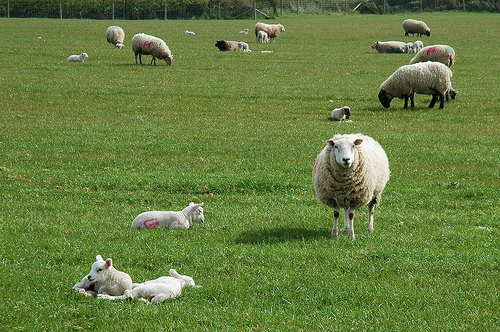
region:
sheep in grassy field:
[288, 119, 387, 248]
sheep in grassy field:
[123, 200, 214, 247]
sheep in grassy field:
[78, 254, 128, 308]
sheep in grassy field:
[151, 265, 195, 310]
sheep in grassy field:
[316, 97, 356, 121]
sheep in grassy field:
[380, 65, 456, 115]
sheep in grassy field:
[411, 45, 459, 62]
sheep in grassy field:
[132, 37, 173, 69]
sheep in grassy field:
[68, 49, 88, 64]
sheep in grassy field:
[98, 14, 122, 56]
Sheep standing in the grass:
[311, 132, 391, 239]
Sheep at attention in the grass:
[308, 132, 392, 237]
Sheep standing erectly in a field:
[309, 132, 392, 238]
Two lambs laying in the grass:
[68, 247, 203, 309]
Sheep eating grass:
[128, 30, 177, 70]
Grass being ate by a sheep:
[130, 31, 175, 67]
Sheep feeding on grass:
[128, 31, 175, 66]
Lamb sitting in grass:
[66, 50, 88, 63]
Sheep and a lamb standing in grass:
[252, 19, 287, 46]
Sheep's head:
[325, 136, 363, 169]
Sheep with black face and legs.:
[375, 60, 455, 110]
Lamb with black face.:
[326, 102, 348, 117]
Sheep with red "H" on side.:
[130, 30, 175, 65]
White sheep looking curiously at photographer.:
[307, 130, 387, 240]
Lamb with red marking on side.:
[129, 199, 206, 232]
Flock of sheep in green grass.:
[64, 18, 461, 306]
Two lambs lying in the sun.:
[72, 252, 204, 307]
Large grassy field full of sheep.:
[1, 16, 498, 328]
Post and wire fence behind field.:
[1, 0, 499, 17]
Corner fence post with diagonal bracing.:
[236, 0, 271, 18]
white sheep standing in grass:
[302, 131, 404, 242]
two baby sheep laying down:
[73, 250, 230, 310]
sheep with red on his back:
[416, 40, 459, 62]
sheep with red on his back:
[128, 30, 185, 72]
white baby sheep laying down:
[65, 45, 97, 68]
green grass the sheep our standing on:
[171, 87, 280, 190]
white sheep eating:
[369, 59, 457, 124]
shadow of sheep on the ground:
[230, 206, 330, 260]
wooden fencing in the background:
[15, 0, 226, 18]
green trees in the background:
[356, 2, 498, 12]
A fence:
[1, 0, 399, 19]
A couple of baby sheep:
[70, 250, 211, 317]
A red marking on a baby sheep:
[141, 214, 163, 229]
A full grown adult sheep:
[309, 125, 394, 247]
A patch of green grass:
[310, 257, 420, 321]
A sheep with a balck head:
[376, 59, 451, 110]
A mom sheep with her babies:
[369, 36, 423, 55]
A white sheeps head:
[324, 137, 365, 169]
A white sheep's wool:
[348, 172, 374, 189]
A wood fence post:
[251, 1, 256, 21]